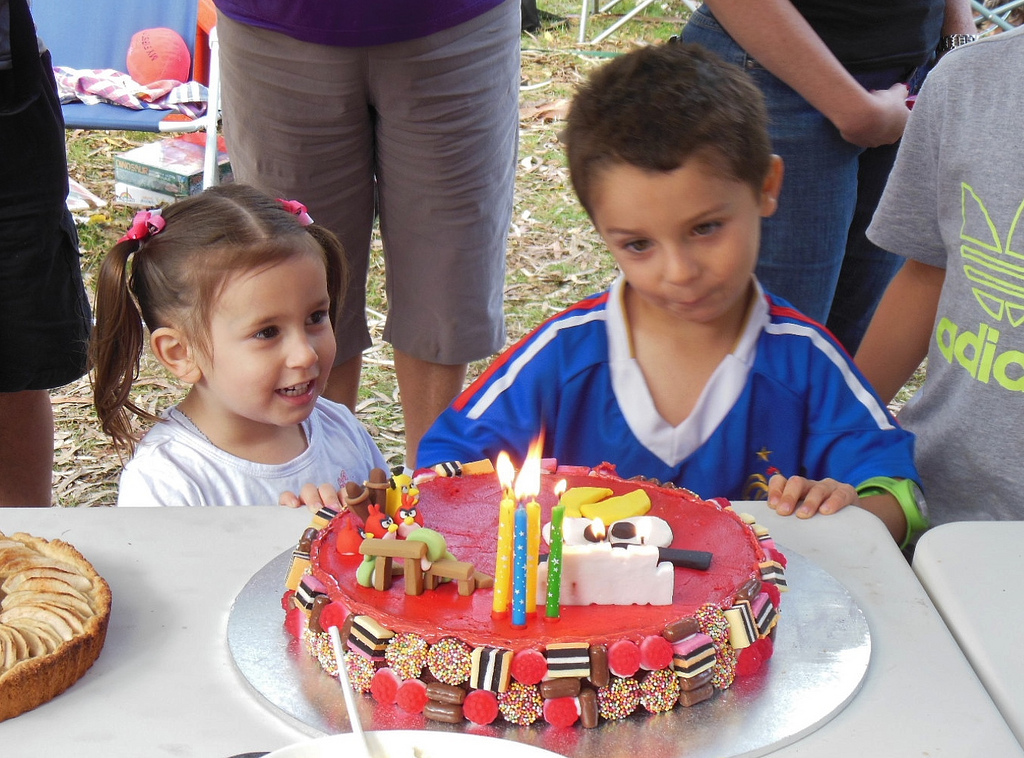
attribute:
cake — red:
[284, 438, 784, 730]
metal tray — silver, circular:
[224, 529, 869, 755]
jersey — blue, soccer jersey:
[415, 270, 916, 485]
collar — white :
[594, 275, 772, 465]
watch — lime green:
[853, 465, 931, 529]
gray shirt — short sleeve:
[842, 25, 1021, 523]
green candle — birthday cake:
[546, 506, 573, 615]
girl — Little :
[88, 182, 406, 503]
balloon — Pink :
[127, 27, 208, 89]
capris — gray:
[212, 1, 525, 385]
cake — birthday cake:
[368, 422, 774, 699]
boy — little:
[412, 36, 937, 552]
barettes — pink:
[115, 186, 334, 253]